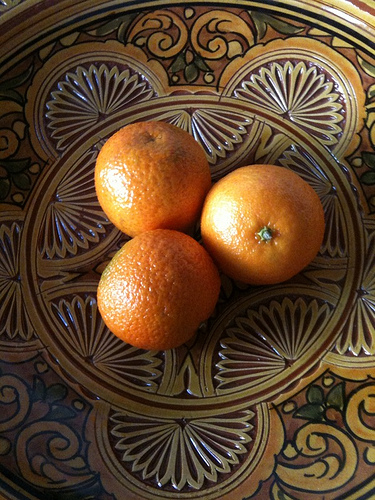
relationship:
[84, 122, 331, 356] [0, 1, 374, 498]
group on tile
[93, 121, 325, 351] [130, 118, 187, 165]
orange with spot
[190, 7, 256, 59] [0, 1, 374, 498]
design on tile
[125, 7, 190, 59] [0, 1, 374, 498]
design on tile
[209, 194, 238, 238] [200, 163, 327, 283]
reflection on skin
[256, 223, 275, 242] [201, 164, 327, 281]
stem on orange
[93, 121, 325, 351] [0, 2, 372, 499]
orange on plate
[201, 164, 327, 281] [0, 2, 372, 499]
orange on plate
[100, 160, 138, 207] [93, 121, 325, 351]
reflection on orange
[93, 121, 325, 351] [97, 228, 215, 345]
orange with rind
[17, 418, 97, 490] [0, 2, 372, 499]
pattern on plate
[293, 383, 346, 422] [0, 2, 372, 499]
pattern on plate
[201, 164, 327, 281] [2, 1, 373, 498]
orange on table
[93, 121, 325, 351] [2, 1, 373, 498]
orange on table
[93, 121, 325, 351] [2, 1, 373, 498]
orange are on table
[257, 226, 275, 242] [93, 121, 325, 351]
stem on orange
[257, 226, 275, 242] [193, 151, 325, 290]
stem on orange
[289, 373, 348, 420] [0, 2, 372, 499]
leaf on plate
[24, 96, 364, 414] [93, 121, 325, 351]
circle under orange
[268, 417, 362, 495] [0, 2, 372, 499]
design on plate